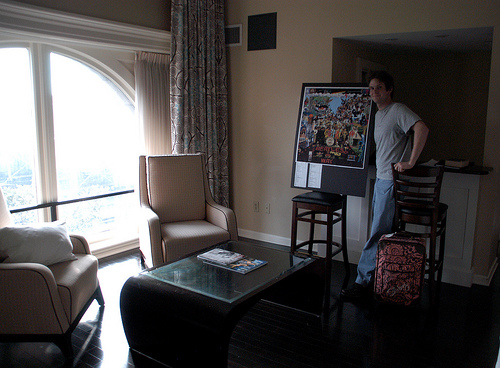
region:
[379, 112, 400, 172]
part of a grey top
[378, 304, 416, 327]
part of the floor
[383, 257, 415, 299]
part of a bag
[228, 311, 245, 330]
edge of a table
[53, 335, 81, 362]
stand of a sofa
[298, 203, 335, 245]
part of a stool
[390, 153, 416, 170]
part of a hand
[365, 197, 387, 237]
part of a trouser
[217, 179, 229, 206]
part of a curtain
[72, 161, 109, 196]
part of a window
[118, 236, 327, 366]
Black coffee table with glass on top.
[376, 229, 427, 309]
Pink and black floral suitcase.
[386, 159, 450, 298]
Tall dark brown bar stool a man has his hand on.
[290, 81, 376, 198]
Board with a picture on it beside a man.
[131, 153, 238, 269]
Light colored chair to the right of the window.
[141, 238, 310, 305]
Glass top of a coffee table.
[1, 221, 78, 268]
White pillow on a chair.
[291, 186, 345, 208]
Black part of a bar stool seat with a black board on it.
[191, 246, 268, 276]
Two magazines on a black coffee table.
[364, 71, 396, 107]
Dark haired head of a smiling man.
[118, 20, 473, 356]
Man holding a piece of art.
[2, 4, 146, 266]
Large arched window.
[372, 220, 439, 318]
Pink rolling suitcase.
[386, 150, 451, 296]
A bar stool on the right.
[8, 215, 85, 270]
Square pillow in chair on left.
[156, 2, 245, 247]
Long ceiling to floor drapes.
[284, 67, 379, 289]
Piece of art resting on stool.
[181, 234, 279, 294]
Magazines laying on coffee table.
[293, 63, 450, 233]
Man standing between picture chair.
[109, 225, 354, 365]
Coffee table with glass top.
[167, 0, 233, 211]
floor to ceiling draperies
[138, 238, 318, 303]
glass covering on coffee table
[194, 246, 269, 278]
two neatly stacked magazines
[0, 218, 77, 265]
pillow with wrinkled pillow case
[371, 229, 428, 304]
pink and black luggage piece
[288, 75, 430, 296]
man posing for a picture being taken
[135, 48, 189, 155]
curtains pulled back to display window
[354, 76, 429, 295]
man wearing short shirt and blue pants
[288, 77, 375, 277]
stool with large photograph resting on it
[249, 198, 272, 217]
two unused wall sockets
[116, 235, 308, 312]
Coffee table in a room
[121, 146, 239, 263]
Beige chair in a room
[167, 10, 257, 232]
Curtain on a wall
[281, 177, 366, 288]
Brown bar stool on a counter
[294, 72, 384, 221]
Sign on a chair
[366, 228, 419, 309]
Suitcase by a chair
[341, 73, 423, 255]
Man in a gray t-shirt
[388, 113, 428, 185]
Arm on a chair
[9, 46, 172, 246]
Window with light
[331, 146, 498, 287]
Bar with molding